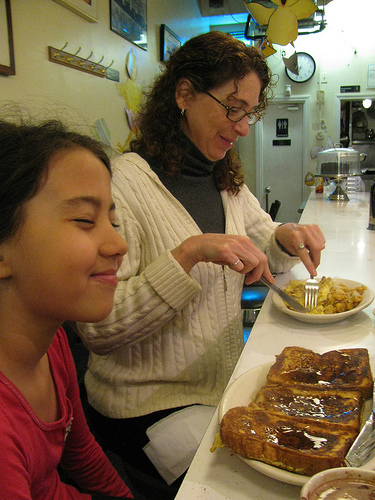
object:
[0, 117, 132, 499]
girl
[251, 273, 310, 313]
knife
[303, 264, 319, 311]
fork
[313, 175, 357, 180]
cake pan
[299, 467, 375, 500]
cup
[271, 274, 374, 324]
bowl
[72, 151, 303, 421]
sweater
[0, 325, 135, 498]
shirt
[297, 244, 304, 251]
ring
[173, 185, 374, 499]
table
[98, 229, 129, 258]
nose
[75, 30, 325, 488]
woman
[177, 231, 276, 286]
hand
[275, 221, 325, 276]
hand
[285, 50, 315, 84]
clock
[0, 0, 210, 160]
wall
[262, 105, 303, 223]
door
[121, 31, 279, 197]
hair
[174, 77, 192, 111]
ear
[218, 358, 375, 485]
plate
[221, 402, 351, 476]
french toast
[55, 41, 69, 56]
hooks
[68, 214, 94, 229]
eyes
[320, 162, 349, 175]
cake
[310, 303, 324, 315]
food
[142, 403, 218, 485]
napkin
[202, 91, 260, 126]
glasses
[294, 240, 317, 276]
finger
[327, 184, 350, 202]
stand